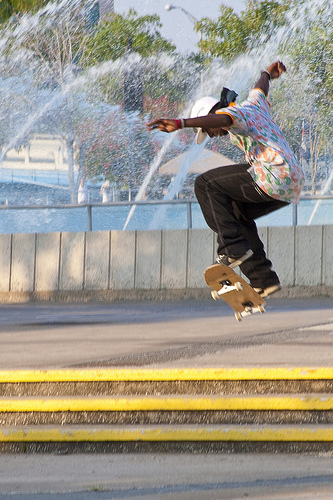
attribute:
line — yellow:
[2, 367, 332, 385]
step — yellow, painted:
[0, 365, 330, 398]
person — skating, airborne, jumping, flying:
[143, 62, 298, 296]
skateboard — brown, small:
[202, 261, 268, 325]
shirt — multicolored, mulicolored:
[216, 88, 307, 200]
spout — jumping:
[119, 2, 328, 226]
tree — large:
[50, 10, 153, 203]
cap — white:
[186, 96, 219, 145]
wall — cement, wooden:
[0, 224, 330, 304]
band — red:
[177, 117, 187, 131]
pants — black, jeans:
[192, 162, 280, 283]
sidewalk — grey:
[0, 302, 331, 367]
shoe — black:
[212, 247, 253, 269]